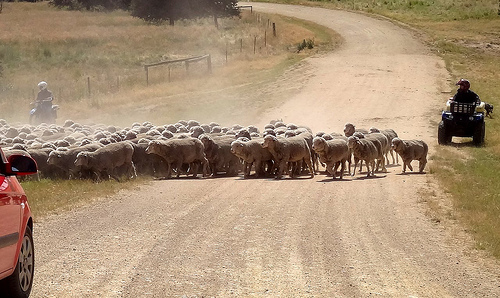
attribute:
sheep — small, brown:
[308, 135, 349, 177]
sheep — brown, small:
[347, 136, 380, 176]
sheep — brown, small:
[391, 135, 431, 174]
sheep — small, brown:
[229, 131, 259, 169]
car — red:
[2, 132, 102, 297]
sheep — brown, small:
[262, 133, 315, 179]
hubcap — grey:
[16, 232, 35, 292]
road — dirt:
[19, 0, 486, 286]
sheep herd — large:
[2, 113, 429, 183]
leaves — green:
[54, 1, 246, 26]